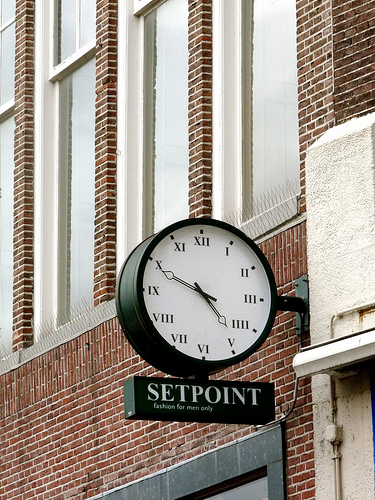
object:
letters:
[145, 381, 264, 409]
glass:
[198, 470, 268, 497]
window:
[138, 1, 193, 242]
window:
[55, 0, 94, 319]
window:
[0, 2, 12, 361]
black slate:
[195, 426, 283, 498]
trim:
[81, 422, 286, 498]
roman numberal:
[193, 236, 210, 246]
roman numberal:
[223, 246, 229, 256]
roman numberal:
[239, 267, 247, 276]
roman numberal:
[232, 320, 249, 329]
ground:
[294, 87, 329, 136]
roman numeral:
[152, 312, 174, 323]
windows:
[231, 0, 301, 227]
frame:
[290, 325, 369, 374]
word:
[202, 404, 214, 412]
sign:
[131, 376, 276, 424]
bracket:
[279, 275, 310, 335]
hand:
[193, 281, 228, 328]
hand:
[162, 270, 217, 301]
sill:
[32, 307, 95, 354]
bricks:
[0, 0, 375, 500]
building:
[0, 0, 375, 500]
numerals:
[244, 294, 257, 304]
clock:
[116, 217, 303, 375]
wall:
[0, 0, 362, 497]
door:
[89, 430, 281, 500]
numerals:
[149, 238, 258, 351]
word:
[145, 380, 259, 406]